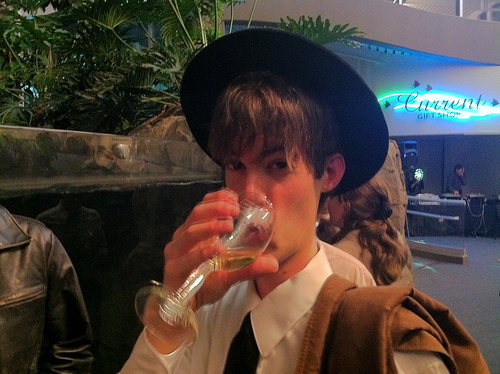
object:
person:
[109, 28, 460, 373]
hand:
[141, 185, 278, 329]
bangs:
[205, 85, 310, 175]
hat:
[179, 27, 391, 197]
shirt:
[115, 241, 451, 374]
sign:
[372, 81, 499, 125]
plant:
[268, 11, 371, 46]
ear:
[316, 150, 348, 192]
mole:
[281, 268, 290, 276]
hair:
[204, 71, 347, 176]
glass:
[133, 188, 275, 346]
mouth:
[240, 222, 276, 249]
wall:
[363, 64, 500, 237]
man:
[439, 162, 468, 196]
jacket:
[288, 269, 493, 373]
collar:
[212, 238, 334, 360]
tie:
[213, 310, 264, 374]